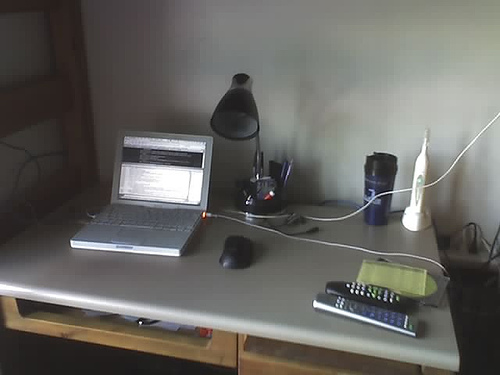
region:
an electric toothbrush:
[406, 125, 433, 236]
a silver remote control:
[313, 294, 423, 336]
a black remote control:
[323, 278, 415, 310]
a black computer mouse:
[218, 235, 255, 270]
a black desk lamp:
[210, 74, 287, 220]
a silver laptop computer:
[73, 127, 212, 257]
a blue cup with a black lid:
[362, 149, 396, 226]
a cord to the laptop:
[213, 213, 457, 275]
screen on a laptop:
[121, 133, 206, 206]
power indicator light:
[200, 208, 210, 220]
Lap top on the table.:
[68, 54, 231, 365]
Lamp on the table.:
[184, 59, 356, 241]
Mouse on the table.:
[198, 212, 266, 284]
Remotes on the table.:
[294, 245, 451, 360]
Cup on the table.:
[346, 128, 401, 232]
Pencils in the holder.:
[214, 146, 293, 221]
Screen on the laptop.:
[97, 110, 237, 212]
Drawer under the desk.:
[23, 286, 219, 374]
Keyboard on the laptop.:
[76, 167, 203, 268]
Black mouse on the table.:
[197, 220, 350, 344]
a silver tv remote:
[314, 288, 424, 338]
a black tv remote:
[326, 280, 423, 310]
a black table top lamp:
[209, 68, 291, 214]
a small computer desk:
[0, 165, 460, 367]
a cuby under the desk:
[0, 289, 233, 364]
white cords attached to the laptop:
[211, 111, 496, 273]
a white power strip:
[440, 240, 496, 262]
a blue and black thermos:
[362, 149, 396, 228]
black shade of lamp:
[214, 74, 259, 141]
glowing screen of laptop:
[119, 135, 205, 205]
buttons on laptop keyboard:
[96, 208, 200, 229]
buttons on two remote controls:
[329, 282, 406, 326]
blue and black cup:
[361, 151, 398, 223]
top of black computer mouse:
[218, 234, 255, 269]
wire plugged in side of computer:
[196, 209, 445, 271]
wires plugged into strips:
[432, 220, 497, 267]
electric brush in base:
[400, 130, 434, 232]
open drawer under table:
[16, 298, 221, 348]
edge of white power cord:
[186, 207, 223, 228]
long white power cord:
[255, 220, 437, 270]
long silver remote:
[306, 304, 421, 334]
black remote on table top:
[319, 269, 424, 308]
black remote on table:
[214, 223, 265, 278]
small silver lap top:
[67, 122, 237, 267]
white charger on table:
[394, 127, 443, 252]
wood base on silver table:
[34, 310, 144, 360]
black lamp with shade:
[195, 76, 287, 225]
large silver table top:
[21, 162, 451, 344]